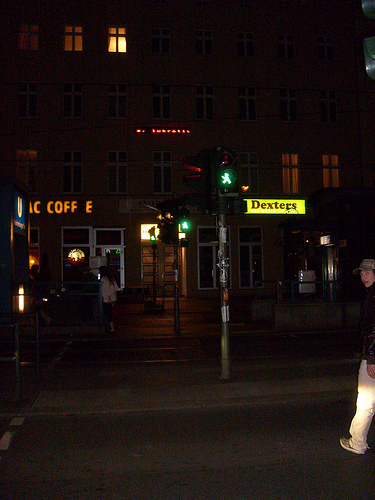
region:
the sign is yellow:
[240, 183, 332, 247]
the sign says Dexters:
[238, 191, 324, 231]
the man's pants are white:
[333, 329, 366, 460]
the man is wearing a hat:
[341, 242, 373, 296]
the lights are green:
[150, 166, 276, 241]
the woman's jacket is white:
[84, 269, 132, 307]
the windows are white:
[60, 220, 133, 299]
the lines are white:
[0, 414, 63, 480]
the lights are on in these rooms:
[14, 23, 135, 58]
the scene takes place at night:
[5, 1, 373, 496]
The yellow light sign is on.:
[234, 194, 288, 232]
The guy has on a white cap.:
[344, 252, 374, 271]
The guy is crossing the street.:
[344, 261, 372, 458]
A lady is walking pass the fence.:
[95, 262, 127, 331]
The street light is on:
[209, 159, 240, 391]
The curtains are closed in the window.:
[279, 154, 300, 207]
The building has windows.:
[57, 80, 298, 135]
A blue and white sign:
[14, 192, 33, 241]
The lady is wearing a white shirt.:
[91, 271, 119, 303]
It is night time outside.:
[47, 132, 332, 393]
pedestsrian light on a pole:
[189, 139, 286, 385]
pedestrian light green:
[204, 156, 242, 226]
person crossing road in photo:
[303, 220, 368, 498]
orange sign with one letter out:
[15, 187, 127, 230]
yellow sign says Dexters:
[245, 171, 327, 234]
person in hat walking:
[347, 232, 373, 420]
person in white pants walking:
[347, 236, 373, 466]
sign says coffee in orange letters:
[23, 185, 128, 227]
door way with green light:
[99, 193, 216, 366]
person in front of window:
[50, 255, 135, 367]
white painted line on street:
[0, 408, 32, 472]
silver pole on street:
[210, 304, 231, 400]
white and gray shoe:
[309, 435, 366, 470]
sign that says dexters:
[233, 190, 303, 232]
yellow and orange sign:
[241, 190, 305, 229]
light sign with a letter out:
[25, 194, 98, 236]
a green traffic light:
[204, 161, 246, 198]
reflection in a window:
[45, 226, 98, 284]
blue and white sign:
[2, 192, 27, 239]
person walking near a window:
[51, 244, 134, 340]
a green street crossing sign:
[218, 167, 237, 187]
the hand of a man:
[362, 362, 373, 380]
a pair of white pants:
[345, 358, 373, 450]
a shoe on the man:
[337, 433, 368, 456]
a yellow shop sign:
[240, 191, 309, 221]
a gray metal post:
[212, 203, 235, 379]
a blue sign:
[8, 193, 29, 234]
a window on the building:
[101, 22, 132, 56]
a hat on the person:
[349, 253, 374, 274]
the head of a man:
[350, 255, 374, 289]